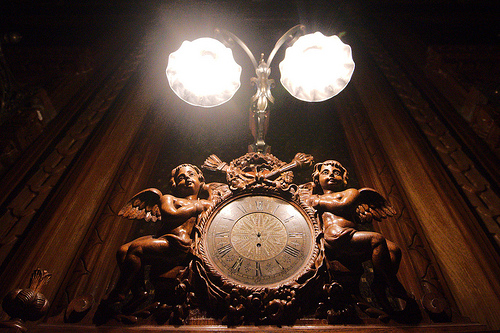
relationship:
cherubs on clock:
[105, 154, 420, 323] [192, 177, 327, 298]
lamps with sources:
[153, 25, 363, 121] [165, 29, 353, 111]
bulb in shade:
[197, 46, 224, 78] [157, 34, 245, 112]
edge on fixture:
[276, 26, 364, 113] [145, 16, 367, 209]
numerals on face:
[216, 199, 304, 280] [198, 190, 320, 284]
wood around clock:
[189, 148, 332, 321] [192, 177, 327, 298]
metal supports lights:
[206, 17, 309, 158] [154, 21, 375, 118]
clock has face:
[192, 177, 327, 298] [198, 190, 320, 284]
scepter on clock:
[197, 146, 317, 190] [192, 177, 327, 298]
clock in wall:
[192, 177, 327, 298] [1, 1, 499, 332]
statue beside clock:
[4, 261, 54, 325] [192, 177, 327, 298]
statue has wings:
[108, 153, 216, 314] [119, 186, 200, 225]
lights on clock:
[154, 21, 375, 118] [192, 177, 327, 298]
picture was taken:
[0, 0, 500, 333] [10, 9, 463, 251]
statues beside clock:
[103, 148, 415, 317] [192, 177, 327, 298]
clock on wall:
[192, 177, 327, 298] [1, 1, 499, 332]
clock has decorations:
[192, 177, 327, 298] [86, 140, 425, 331]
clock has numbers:
[192, 177, 327, 298] [205, 197, 320, 294]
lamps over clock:
[153, 25, 363, 121] [192, 177, 327, 298]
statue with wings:
[108, 153, 216, 314] [119, 186, 200, 225]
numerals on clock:
[216, 199, 304, 280] [192, 177, 327, 298]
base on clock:
[105, 289, 405, 331] [192, 177, 327, 298]